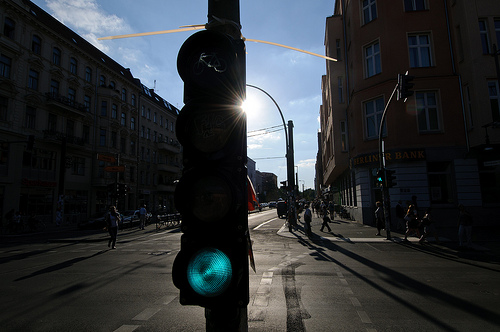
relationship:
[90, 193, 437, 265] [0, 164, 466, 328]
people on road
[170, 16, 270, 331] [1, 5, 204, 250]
light near building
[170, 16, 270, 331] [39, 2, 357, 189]
light under sky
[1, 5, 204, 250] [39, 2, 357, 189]
building under sky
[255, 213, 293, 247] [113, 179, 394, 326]
dash in road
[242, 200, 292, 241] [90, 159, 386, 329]
dash in road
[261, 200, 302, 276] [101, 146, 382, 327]
dash in road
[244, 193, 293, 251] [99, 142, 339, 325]
dash in road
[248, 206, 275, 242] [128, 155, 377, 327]
dash in road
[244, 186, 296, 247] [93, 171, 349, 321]
dash in road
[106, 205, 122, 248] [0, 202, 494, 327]
person in road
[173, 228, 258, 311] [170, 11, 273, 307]
traffic light on pole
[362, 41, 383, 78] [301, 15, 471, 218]
window on building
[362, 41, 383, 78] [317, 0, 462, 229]
window on building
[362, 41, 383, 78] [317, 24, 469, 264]
window on building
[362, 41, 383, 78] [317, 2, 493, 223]
window on building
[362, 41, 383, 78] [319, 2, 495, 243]
window on building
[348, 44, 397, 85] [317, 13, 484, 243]
window on building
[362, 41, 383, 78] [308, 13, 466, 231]
window on building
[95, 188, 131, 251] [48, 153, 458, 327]
person walking on street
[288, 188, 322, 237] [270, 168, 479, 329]
person walking on sidewalk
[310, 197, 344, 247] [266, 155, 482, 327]
person walking on sidewalk